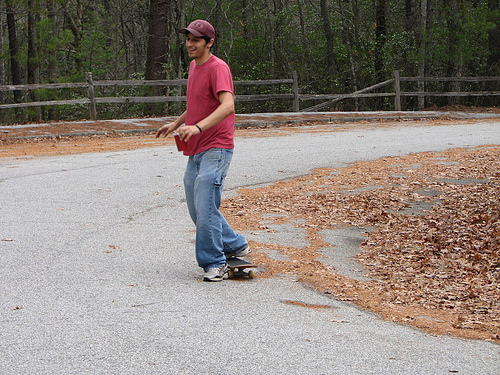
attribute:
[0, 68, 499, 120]
fence — corral, wooden, brown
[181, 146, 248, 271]
blue jeans — over sized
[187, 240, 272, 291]
sneakers — blue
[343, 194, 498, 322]
pile leaves — gold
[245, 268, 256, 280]
wheel — under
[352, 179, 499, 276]
brown leaves — dead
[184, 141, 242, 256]
jeans — blue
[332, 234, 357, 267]
spot — bare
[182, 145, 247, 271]
jeans — blue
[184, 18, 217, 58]
head — man's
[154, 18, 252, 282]
man — young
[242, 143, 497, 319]
leaves — many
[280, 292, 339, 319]
spot — brown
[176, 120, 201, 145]
hand — man's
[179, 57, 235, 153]
shirt — red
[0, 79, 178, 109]
fence — wood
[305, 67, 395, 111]
piece — down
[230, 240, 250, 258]
foot — one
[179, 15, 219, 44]
cap — maroon, baseball